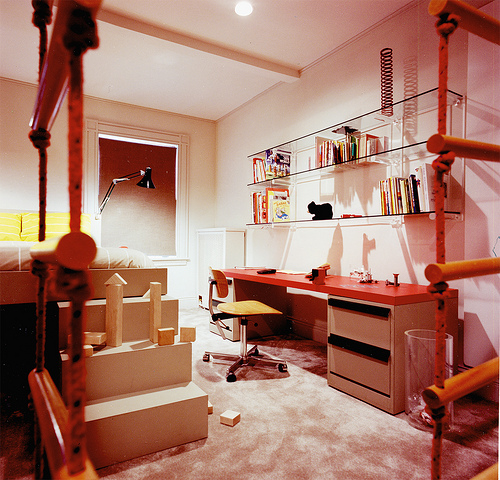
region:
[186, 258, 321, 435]
Chair sitting by the desk.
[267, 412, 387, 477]
The carpet has been recently vacuumed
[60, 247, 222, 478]
Steps going up to bed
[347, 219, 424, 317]
shadow on the wall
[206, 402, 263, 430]
Block of wood on the floor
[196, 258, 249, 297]
Back on the chair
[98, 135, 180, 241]
Light hanging on the wall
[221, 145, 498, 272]
Books on the shelf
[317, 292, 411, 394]
Shelf under the desk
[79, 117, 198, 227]
Doorway into the room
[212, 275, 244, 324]
a chair on the floor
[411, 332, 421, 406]
a glass dust bin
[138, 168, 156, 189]
an office lamp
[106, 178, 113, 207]
a lamp stand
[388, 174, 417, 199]
books on a shelve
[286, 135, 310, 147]
a shelve made of glass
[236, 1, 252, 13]
a lit bulb on the ceiling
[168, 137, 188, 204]
a window frame on the wall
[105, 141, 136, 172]
a window in the room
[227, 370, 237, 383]
the wheel of the chair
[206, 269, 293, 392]
A small arm chair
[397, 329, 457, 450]
A glass rubish bin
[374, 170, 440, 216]
A glass book shelf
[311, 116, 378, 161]
Books arranged on a shelf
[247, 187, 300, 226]
Books arranged on a shelf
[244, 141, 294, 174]
Books arranged on a shelf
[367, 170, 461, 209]
Books arranged on a shelf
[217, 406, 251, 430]
A piece of wood on the floor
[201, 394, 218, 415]
A piece of wood on the floor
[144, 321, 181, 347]
A piece of wood on the bed stair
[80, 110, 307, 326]
a lamp is in the window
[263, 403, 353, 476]
the brown carpet is clean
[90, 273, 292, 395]
blocks of wood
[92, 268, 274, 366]
pieces of wood is grouped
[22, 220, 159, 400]
the bar is made of rope and wood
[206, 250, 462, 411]
the desk has drawers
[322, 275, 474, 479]
two drawers are on the desk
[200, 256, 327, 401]
an office chair is by the desk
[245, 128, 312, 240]
books are on the shelf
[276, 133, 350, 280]
the bookcase is clear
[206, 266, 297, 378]
the chair is wooden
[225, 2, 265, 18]
light is on the ceiling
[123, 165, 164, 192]
the lamp is black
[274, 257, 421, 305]
the surface is red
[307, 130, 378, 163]
books are on the shelf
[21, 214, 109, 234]
the pillow is yellow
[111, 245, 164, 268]
the matress is brown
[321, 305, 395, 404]
the cabinet is brown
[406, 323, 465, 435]
the trash can is made of glass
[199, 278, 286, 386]
the chair has wheels